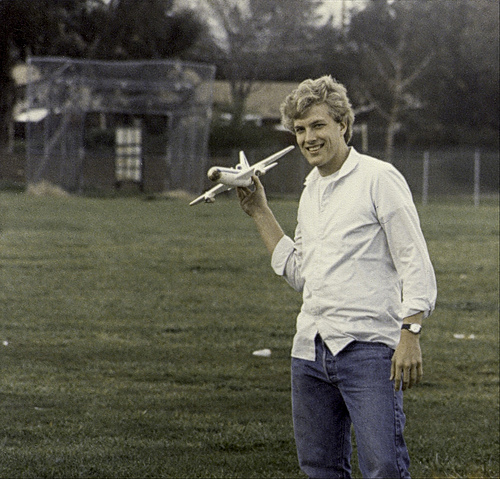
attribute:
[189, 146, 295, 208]
airplane — toy, model, white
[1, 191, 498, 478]
grass — long, green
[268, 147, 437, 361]
shirt — white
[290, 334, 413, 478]
pants — blue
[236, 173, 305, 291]
arm — raised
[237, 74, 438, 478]
man — smiling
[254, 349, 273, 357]
trash — white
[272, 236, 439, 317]
sleeves — folded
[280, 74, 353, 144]
hair — brown, blonde